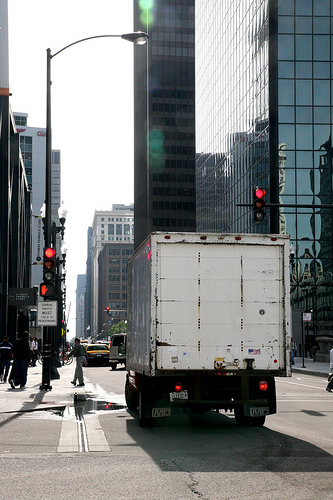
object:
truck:
[123, 229, 294, 431]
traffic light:
[39, 243, 57, 297]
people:
[8, 330, 35, 388]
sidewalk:
[0, 383, 58, 420]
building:
[192, 0, 271, 234]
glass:
[277, 77, 295, 104]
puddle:
[50, 389, 125, 424]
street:
[0, 357, 333, 500]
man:
[66, 337, 87, 387]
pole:
[40, 48, 55, 247]